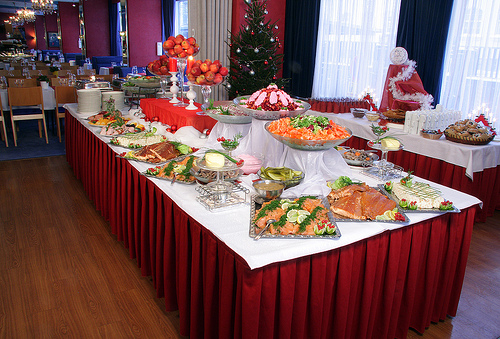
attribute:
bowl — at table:
[287, 137, 329, 155]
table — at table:
[59, 86, 475, 336]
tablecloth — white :
[74, 98, 471, 256]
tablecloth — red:
[58, 177, 468, 332]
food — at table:
[254, 199, 322, 231]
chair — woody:
[11, 78, 56, 142]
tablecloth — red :
[157, 200, 267, 322]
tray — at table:
[233, 182, 340, 252]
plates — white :
[75, 87, 103, 120]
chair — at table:
[8, 85, 48, 138]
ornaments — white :
[253, 48, 257, 52]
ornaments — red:
[236, 48, 239, 53]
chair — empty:
[54, 79, 79, 139]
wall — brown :
[261, 81, 368, 108]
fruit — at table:
[180, 54, 228, 86]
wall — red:
[230, 1, 285, 93]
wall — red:
[127, 1, 163, 65]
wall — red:
[81, 0, 112, 57]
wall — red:
[56, 3, 84, 54]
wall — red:
[44, 13, 58, 50]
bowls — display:
[146, 31, 227, 114]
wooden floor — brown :
[0, 152, 498, 336]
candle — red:
[167, 56, 178, 71]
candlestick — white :
[166, 70, 179, 102]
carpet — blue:
[5, 156, 494, 337]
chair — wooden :
[10, 83, 49, 142]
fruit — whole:
[199, 62, 224, 74]